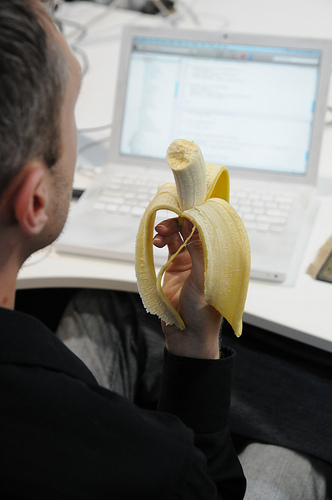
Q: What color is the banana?
A: White and yellow.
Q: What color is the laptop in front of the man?
A: White.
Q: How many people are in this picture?
A: One.